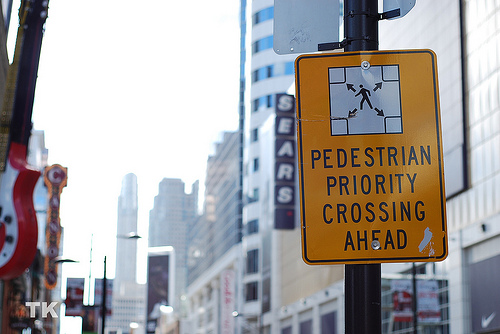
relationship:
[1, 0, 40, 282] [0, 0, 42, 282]
guitar on sign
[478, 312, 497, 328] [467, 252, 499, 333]
logo on sign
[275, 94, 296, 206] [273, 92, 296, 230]
sears on sign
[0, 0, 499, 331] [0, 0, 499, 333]
photo of cityscape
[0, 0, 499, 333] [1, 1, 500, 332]
cityscape in day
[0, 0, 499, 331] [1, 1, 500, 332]
photo in day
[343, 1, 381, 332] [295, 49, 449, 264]
pole holding sign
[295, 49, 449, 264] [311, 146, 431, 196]
sign says pedestrian priority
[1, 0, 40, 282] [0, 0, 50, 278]
guitar sticking out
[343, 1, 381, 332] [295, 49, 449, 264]
pole has pedestrian sign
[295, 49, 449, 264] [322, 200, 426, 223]
sign for crossing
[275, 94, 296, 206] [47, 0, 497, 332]
sears in background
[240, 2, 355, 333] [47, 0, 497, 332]
building in background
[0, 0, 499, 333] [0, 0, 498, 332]
cityscape in distance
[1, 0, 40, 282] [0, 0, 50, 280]
guitar on left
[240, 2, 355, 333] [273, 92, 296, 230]
building has a sign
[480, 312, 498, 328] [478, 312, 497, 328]
logo for logo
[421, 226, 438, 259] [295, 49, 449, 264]
scratch on sign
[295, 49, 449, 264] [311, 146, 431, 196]
sign for pedestrian priority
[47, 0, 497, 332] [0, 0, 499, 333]
background has cityscape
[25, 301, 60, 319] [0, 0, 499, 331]
tk letters on picture